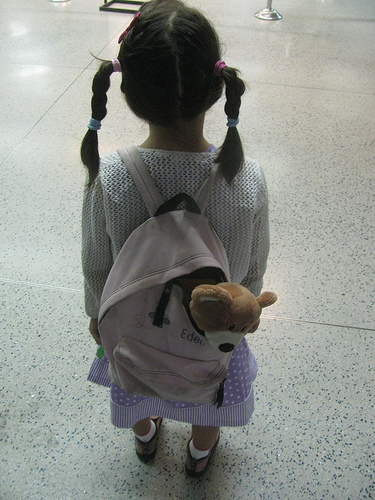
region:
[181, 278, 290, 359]
teddybear is in the bag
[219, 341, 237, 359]
the nose is black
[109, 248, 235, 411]
the bag is open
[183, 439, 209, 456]
the socks are white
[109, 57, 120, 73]
the hairband is pink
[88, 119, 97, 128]
the hairband is blue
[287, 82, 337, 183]
the floor is made of granite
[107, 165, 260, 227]
the sweater is white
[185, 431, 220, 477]
the shoes are brown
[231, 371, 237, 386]
white dot on skirt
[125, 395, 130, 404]
white dot on skirt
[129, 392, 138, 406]
white dot on skirt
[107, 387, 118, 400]
white dot on skirt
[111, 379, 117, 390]
white dot on skirt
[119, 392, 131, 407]
white dot on skirt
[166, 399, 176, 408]
white dot on skirt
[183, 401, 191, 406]
white dot on skirt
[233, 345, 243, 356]
white dot on skirt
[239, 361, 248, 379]
white dot on skirt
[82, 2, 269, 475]
A dark haired girl with pig tails.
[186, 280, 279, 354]
A brown teddy bear in a back pack.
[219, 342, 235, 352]
Black nose of a bear.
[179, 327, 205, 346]
The name Eden on a backpack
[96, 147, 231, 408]
A grey backpack on a girl's back.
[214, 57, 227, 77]
A darker pink hair tie in a girls hair.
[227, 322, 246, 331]
Two black eyes on a bear.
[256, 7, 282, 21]
The round base of a metal pole.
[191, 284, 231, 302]
The larger ear of a bear that's brown and white in the middle.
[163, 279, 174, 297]
The black zipper on a backpack by the bears ear.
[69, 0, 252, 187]
Hair wrapped with bands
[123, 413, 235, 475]
Feet in socks and shoes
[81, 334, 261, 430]
Violet cloth with white spots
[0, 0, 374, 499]
Clear shiny reflective floor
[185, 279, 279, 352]
Head of a doll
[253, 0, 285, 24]
Shiny silver metal stand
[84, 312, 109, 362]
Hand carrying a green object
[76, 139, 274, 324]
Whitish grey long sleeved sweater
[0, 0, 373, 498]
Girl standing on a floor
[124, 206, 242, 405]
the bag is open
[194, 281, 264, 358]
the teddy bear is in the bag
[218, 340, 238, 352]
the nose is black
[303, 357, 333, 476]
the floor is tiled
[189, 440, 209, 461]
the socks are white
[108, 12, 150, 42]
hair clip is on the hair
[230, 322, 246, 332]
the eyes are black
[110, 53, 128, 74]
the hair band is pink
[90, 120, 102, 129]
the hair band is green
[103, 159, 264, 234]
the sweater is white